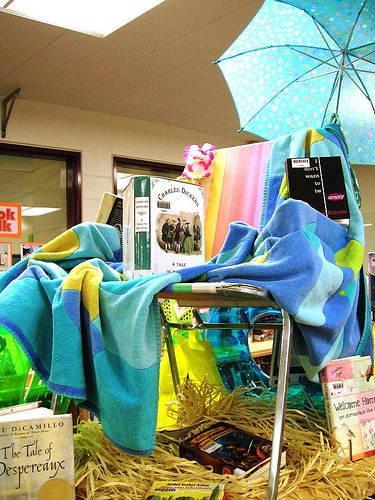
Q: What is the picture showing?
A: It is showing a display.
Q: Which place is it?
A: It is a display.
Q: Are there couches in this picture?
A: No, there are no couches.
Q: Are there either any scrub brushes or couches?
A: No, there are no couches or scrub brushes.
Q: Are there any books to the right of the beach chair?
A: Yes, there is a book to the right of the beach chair.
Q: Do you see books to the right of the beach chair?
A: Yes, there is a book to the right of the beach chair.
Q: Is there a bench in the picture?
A: No, there are no benches.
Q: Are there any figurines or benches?
A: No, there are no benches or figurines.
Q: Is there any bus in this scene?
A: No, there are no buses.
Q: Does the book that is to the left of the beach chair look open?
A: Yes, the book is open.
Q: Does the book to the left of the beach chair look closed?
A: No, the book is open.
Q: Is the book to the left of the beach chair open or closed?
A: The book is open.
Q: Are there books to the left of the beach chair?
A: Yes, there is a book to the left of the beach chair.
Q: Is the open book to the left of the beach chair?
A: Yes, the book is to the left of the beach chair.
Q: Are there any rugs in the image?
A: No, there are no rugs.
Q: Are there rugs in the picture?
A: No, there are no rugs.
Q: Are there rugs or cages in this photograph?
A: No, there are no rugs or cages.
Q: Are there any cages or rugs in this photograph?
A: No, there are no rugs or cages.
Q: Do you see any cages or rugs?
A: No, there are no rugs or cages.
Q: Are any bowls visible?
A: No, there are no bowls.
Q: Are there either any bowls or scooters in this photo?
A: No, there are no bowls or scooters.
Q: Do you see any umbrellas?
A: Yes, there is an umbrella.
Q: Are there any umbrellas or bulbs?
A: Yes, there is an umbrella.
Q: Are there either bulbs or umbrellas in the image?
A: Yes, there is an umbrella.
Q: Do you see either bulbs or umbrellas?
A: Yes, there is an umbrella.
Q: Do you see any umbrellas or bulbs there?
A: Yes, there is an umbrella.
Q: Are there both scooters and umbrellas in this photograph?
A: No, there is an umbrella but no scooters.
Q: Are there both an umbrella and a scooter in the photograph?
A: No, there is an umbrella but no scooters.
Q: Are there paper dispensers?
A: No, there are no paper dispensers.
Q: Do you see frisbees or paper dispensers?
A: No, there are no paper dispensers or frisbees.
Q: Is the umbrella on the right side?
A: Yes, the umbrella is on the right of the image.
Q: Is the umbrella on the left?
A: No, the umbrella is on the right of the image.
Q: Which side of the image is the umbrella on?
A: The umbrella is on the right of the image.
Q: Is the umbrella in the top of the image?
A: Yes, the umbrella is in the top of the image.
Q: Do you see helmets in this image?
A: No, there are no helmets.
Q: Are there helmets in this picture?
A: No, there are no helmets.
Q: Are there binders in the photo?
A: No, there are no binders.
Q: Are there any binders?
A: No, there are no binders.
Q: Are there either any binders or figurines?
A: No, there are no binders or figurines.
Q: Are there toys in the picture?
A: No, there are no toys.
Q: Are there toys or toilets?
A: No, there are no toys or toilets.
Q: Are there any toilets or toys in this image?
A: No, there are no toys or toilets.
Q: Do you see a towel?
A: Yes, there is a towel.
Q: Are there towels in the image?
A: Yes, there is a towel.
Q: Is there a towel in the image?
A: Yes, there is a towel.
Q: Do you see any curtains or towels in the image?
A: Yes, there is a towel.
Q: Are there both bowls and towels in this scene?
A: No, there is a towel but no bowls.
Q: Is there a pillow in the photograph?
A: No, there are no pillows.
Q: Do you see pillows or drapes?
A: No, there are no pillows or drapes.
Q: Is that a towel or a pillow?
A: That is a towel.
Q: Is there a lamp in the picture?
A: No, there are no lamps.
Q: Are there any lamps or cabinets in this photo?
A: No, there are no lamps or cabinets.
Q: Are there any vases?
A: No, there are no vases.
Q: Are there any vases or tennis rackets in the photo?
A: No, there are no vases or tennis rackets.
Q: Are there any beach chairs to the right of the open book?
A: Yes, there is a beach chair to the right of the book.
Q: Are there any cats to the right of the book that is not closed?
A: No, there is a beach chair to the right of the book.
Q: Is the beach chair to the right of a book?
A: Yes, the beach chair is to the right of a book.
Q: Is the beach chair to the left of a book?
A: Yes, the beach chair is to the left of a book.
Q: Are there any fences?
A: No, there are no fences.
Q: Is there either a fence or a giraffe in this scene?
A: No, there are no fences or giraffes.